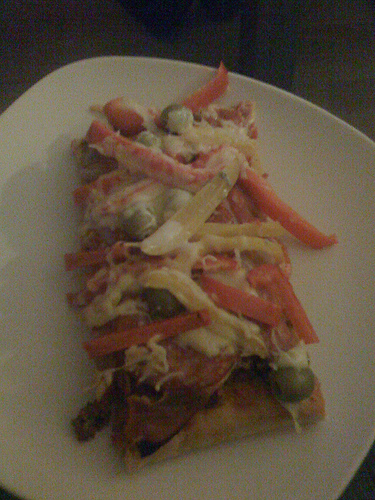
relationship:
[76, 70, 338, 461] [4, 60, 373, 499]
food on plate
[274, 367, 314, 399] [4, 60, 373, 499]
pea on plate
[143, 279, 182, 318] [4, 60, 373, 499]
pea on plate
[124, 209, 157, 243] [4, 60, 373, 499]
pea on plate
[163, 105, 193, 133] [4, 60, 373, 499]
pea on plate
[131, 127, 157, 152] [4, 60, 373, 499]
pea on plate